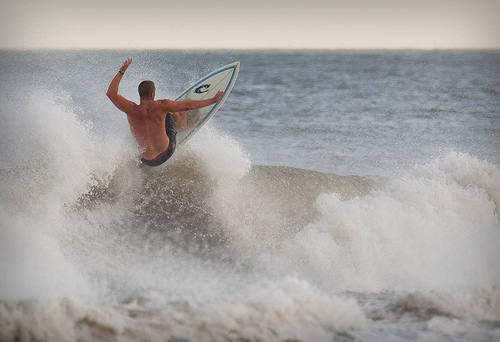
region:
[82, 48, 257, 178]
man on a surfboard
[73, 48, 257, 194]
man surfing a wave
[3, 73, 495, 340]
pretty big wave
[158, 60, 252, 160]
long white surfboard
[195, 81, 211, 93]
design on the surfboard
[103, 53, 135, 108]
arm is bent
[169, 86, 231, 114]
other arm is extended to the side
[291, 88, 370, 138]
small ripples in the water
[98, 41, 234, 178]
man with no shirt on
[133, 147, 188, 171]
behind sticking out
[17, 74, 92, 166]
water being kicked up by the wave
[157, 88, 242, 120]
other arm extended to the side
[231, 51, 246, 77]
pointy tip of the surfboard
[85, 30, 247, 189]
a man riding a surfboard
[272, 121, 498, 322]
waves crashing in the water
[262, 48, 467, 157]
a dark blue ocean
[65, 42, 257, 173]
a man in the water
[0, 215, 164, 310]
white cast off waves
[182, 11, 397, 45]
a gray sky above the ocean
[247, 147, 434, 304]
a white ocean wave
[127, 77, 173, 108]
the head of a man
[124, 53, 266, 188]
a white surfboard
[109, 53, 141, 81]
hand of a man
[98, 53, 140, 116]
arm bent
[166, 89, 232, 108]
other arm extended to the side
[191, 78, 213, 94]
small logo on the surfboard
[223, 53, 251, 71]
pointed edge of the board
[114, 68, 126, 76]
thin wristband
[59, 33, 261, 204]
man surfing in the ocean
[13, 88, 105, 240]
white water form the wave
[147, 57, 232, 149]
white and blue surfboard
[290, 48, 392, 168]
blue ocean with waves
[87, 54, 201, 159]
man topless surfing in water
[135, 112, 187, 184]
guy wearing boardshorts while surfing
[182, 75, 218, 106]
sticker of a C on surfboard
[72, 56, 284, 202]
guy with hand up surfing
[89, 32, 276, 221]
guy jumping wake while surfing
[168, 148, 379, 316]
wave crushing in the water